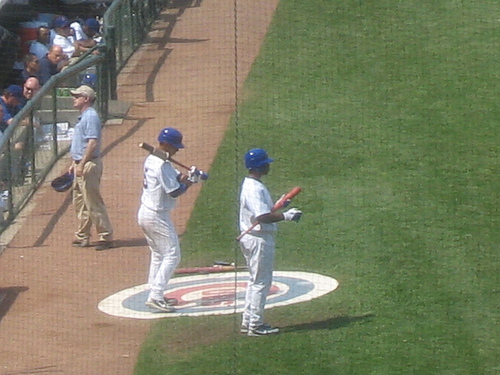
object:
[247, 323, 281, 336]
footwear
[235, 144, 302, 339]
man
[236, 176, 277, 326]
uniform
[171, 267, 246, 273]
baseball bat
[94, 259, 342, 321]
ground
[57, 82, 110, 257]
man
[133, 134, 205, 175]
baseball player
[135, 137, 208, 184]
bat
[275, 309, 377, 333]
shadow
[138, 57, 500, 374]
grass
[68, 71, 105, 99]
baseball cap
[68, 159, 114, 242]
pants